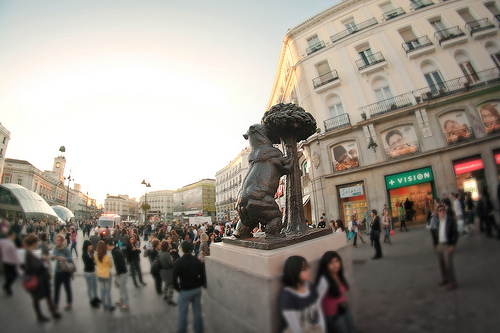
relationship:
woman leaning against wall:
[278, 255, 326, 330] [265, 225, 358, 332]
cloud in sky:
[79, 27, 201, 73] [0, 3, 350, 216]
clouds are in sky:
[57, 17, 229, 157] [0, 3, 350, 216]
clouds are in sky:
[41, 36, 92, 60] [1, 3, 342, 193]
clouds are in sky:
[198, 47, 256, 75] [1, 3, 342, 193]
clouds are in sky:
[142, 40, 178, 61] [1, 3, 342, 193]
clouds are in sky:
[104, 43, 129, 66] [1, 3, 342, 193]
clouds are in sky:
[3, 65, 23, 87] [1, 3, 342, 193]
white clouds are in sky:
[88, 54, 245, 139] [3, 0, 282, 160]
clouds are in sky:
[6, 6, 268, 192] [1, 3, 342, 193]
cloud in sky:
[4, 40, 262, 206] [1, 3, 342, 193]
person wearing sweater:
[170, 241, 207, 331] [172, 254, 200, 281]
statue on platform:
[213, 94, 335, 252] [192, 226, 364, 331]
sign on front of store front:
[383, 162, 433, 192] [376, 161, 447, 228]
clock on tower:
[47, 158, 65, 172] [42, 142, 71, 192]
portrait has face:
[325, 138, 367, 168] [334, 143, 350, 169]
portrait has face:
[377, 123, 419, 153] [385, 135, 404, 150]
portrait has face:
[437, 105, 471, 141] [444, 120, 458, 132]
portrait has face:
[478, 102, 497, 127] [479, 110, 494, 129]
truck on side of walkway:
[93, 212, 120, 239] [7, 218, 499, 331]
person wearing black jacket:
[169, 239, 212, 331] [169, 253, 207, 295]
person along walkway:
[169, 239, 212, 331] [0, 272, 241, 331]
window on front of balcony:
[370, 75, 400, 107] [363, 93, 415, 113]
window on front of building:
[370, 75, 400, 107] [259, 0, 497, 225]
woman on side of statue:
[278, 254, 323, 331] [221, 100, 337, 253]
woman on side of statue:
[312, 247, 357, 332] [221, 100, 337, 253]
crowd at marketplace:
[7, 206, 200, 302] [290, 154, 493, 232]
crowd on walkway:
[7, 206, 200, 302] [11, 216, 495, 320]